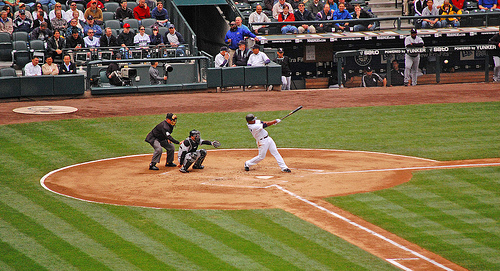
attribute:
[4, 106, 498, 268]
stripes — dark, light 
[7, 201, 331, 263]
grass — short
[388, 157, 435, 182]
line — white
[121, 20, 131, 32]
hat — red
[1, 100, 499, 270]
grass — green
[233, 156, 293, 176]
shoes — black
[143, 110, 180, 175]
umpire — standing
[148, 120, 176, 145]
jacket — black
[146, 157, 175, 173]
shoes — black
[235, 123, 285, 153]
shirts — blue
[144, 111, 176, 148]
jackets — blue